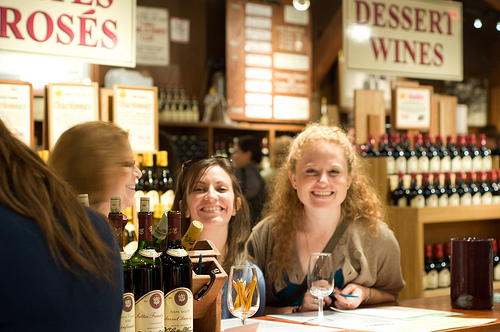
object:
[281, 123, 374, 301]
woman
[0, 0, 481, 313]
photo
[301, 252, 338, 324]
glass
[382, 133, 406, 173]
bottles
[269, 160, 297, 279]
hair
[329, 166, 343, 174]
eye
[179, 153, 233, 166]
goggles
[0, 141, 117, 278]
hair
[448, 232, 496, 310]
vessel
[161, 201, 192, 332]
bottle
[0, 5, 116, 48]
lettering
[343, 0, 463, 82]
sign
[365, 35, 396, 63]
letters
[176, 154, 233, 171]
sunglasses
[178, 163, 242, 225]
head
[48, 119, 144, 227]
woman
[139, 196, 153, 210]
cork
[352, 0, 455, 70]
advertisement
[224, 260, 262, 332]
glasses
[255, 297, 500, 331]
counter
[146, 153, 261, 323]
women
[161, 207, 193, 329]
wine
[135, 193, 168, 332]
bottles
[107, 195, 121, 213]
corks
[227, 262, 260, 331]
glass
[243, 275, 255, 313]
pencils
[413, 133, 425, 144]
tops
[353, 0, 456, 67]
dessert wines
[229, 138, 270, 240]
person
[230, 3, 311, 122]
chart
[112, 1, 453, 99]
background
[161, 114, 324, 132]
shelf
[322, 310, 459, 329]
paper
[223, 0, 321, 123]
signboard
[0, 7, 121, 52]
writings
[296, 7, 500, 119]
area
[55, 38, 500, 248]
store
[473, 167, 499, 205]
wines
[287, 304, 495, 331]
forms